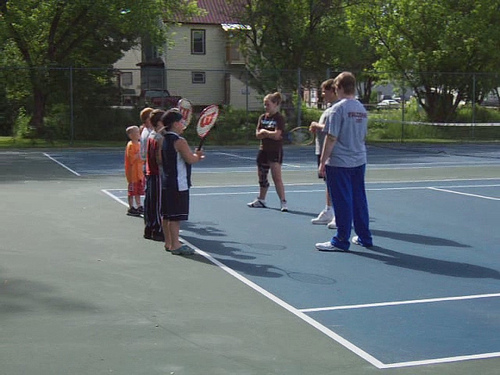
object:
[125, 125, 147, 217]
boy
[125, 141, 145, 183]
shirt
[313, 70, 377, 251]
adults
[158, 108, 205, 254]
boy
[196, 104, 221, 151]
racquet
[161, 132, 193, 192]
tank top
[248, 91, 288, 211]
woman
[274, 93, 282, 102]
ponytail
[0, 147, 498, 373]
tennis court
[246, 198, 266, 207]
tennis shoes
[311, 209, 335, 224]
tennis shoes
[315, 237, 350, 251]
tennis shoes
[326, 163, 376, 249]
pants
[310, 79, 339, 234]
person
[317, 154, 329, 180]
shorts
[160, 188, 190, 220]
shorts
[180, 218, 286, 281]
shadow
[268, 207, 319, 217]
shadow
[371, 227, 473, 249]
shadow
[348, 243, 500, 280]
shadow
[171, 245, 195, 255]
clogs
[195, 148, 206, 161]
hands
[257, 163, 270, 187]
brace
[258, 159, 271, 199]
right leg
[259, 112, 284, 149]
t-shirt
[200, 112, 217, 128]
w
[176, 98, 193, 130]
racquet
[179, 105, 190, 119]
w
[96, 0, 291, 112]
house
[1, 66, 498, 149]
fence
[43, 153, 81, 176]
line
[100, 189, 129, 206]
line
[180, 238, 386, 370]
line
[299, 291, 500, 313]
line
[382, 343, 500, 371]
line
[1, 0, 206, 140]
tree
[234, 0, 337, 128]
tree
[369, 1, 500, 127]
tree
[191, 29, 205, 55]
window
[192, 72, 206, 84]
window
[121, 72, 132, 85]
window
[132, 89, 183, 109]
truck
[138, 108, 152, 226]
boy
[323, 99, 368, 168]
t-shirt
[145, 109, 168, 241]
boy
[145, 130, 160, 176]
shirt